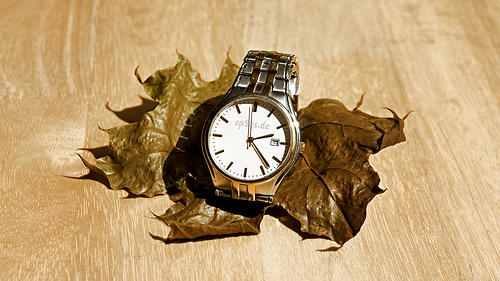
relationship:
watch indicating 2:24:
[198, 49, 307, 205] [210, 104, 287, 179]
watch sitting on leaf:
[198, 49, 307, 205] [281, 103, 417, 245]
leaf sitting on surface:
[303, 95, 412, 162] [2, 130, 94, 266]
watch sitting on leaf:
[203, 93, 307, 202] [102, 52, 206, 190]